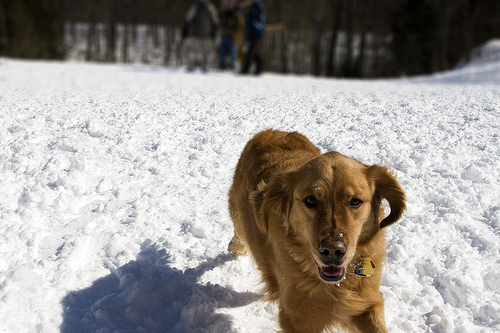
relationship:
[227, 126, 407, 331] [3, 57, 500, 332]
dog in snow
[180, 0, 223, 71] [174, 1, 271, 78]
person in group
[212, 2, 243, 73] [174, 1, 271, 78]
person in group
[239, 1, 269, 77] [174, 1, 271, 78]
person in group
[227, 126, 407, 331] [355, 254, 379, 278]
dog wears tag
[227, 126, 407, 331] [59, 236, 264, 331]
dog casts shadow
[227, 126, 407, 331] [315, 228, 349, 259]
dog has nose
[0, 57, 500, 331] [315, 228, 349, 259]
snow on nose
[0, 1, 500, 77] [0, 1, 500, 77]
tree in tree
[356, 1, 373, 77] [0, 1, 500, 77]
tree in tree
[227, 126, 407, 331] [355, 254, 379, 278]
dog has tag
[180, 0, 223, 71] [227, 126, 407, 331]
person behind dog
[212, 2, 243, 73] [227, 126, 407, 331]
person behind dog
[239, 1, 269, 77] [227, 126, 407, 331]
person behind dog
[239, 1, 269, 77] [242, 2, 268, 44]
person wears jacket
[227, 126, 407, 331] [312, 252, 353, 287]
dog has mouth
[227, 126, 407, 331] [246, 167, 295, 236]
dog has ear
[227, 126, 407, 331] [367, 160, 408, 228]
dog has ear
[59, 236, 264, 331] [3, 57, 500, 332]
shadow in snow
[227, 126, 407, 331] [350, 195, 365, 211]
dog has left eye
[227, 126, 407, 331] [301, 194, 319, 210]
dog has right eye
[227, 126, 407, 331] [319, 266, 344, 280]
dog has tongue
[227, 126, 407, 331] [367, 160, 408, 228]
dog has left ear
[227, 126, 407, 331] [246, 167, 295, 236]
dog has right ear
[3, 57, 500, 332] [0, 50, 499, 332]
snow on ground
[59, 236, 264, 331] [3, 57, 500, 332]
shadow on snow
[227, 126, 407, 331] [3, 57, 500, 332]
dog no snow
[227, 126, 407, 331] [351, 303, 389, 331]
dog has front leg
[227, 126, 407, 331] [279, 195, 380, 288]
dog has neck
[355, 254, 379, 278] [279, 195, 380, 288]
tag around neck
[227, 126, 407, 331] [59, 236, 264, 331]
dog casrs shadow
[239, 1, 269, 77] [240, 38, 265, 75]
person wears pants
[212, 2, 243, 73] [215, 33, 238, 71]
person wears pants